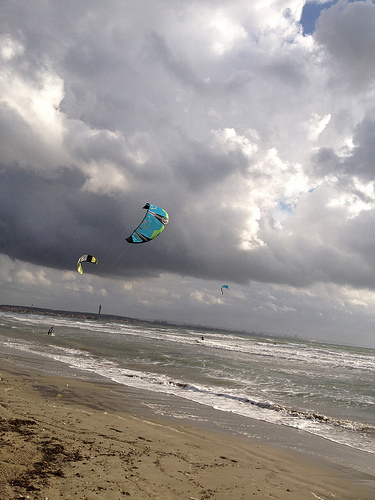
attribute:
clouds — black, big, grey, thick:
[3, 2, 375, 188]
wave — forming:
[178, 378, 194, 393]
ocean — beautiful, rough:
[8, 314, 369, 447]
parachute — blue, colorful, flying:
[129, 201, 170, 250]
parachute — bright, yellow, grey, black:
[75, 253, 98, 278]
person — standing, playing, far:
[45, 327, 54, 339]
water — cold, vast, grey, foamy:
[71, 331, 88, 354]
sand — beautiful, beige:
[3, 447, 277, 498]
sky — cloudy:
[174, 4, 367, 327]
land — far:
[9, 307, 78, 317]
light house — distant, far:
[97, 304, 103, 316]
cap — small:
[42, 427, 45, 430]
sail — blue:
[219, 284, 232, 294]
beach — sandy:
[4, 344, 360, 499]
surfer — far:
[200, 335, 207, 340]